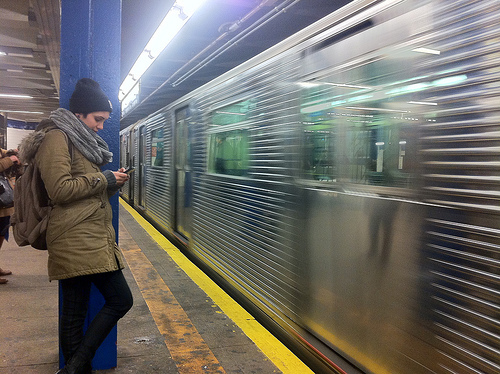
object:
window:
[208, 101, 249, 177]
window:
[151, 127, 164, 166]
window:
[299, 114, 334, 183]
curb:
[116, 193, 356, 374]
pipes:
[123, 0, 301, 122]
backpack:
[13, 162, 49, 251]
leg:
[379, 221, 395, 266]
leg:
[367, 214, 378, 261]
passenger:
[363, 195, 400, 263]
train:
[119, 0, 500, 374]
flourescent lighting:
[119, 0, 198, 98]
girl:
[35, 78, 133, 372]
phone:
[122, 167, 136, 175]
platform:
[0, 191, 318, 374]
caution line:
[117, 196, 316, 372]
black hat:
[70, 78, 113, 113]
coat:
[17, 118, 126, 282]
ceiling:
[120, 0, 348, 129]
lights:
[174, 0, 201, 17]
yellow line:
[114, 221, 235, 374]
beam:
[59, 0, 121, 372]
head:
[69, 78, 113, 134]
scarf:
[49, 108, 114, 165]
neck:
[66, 116, 89, 140]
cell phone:
[123, 167, 136, 174]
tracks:
[122, 184, 336, 372]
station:
[0, 0, 495, 373]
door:
[176, 111, 191, 240]